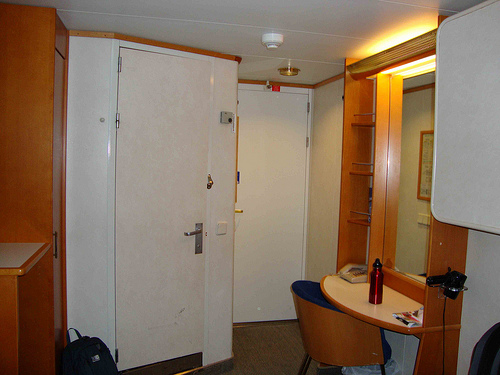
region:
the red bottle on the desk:
[368, 257, 383, 305]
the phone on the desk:
[337, 261, 367, 283]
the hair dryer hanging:
[425, 265, 466, 374]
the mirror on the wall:
[381, 60, 435, 285]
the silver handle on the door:
[182, 230, 200, 235]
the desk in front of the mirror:
[319, 273, 424, 333]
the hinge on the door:
[117, 55, 122, 71]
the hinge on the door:
[115, 113, 120, 128]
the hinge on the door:
[113, 348, 118, 363]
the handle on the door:
[52, 230, 57, 257]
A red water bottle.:
[366, 258, 384, 305]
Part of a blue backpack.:
[61, 324, 117, 374]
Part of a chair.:
[306, 312, 326, 339]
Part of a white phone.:
[340, 260, 370, 282]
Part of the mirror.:
[408, 149, 423, 201]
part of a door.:
[141, 217, 169, 264]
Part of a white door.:
[263, 192, 283, 237]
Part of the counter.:
[11, 245, 21, 257]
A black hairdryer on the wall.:
[428, 268, 468, 298]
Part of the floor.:
[251, 335, 272, 362]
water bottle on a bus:
[362, 254, 397, 306]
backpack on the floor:
[49, 302, 104, 373]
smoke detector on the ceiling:
[258, 31, 285, 49]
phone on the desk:
[336, 250, 371, 281]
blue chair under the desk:
[285, 266, 400, 371]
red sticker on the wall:
[265, 80, 284, 97]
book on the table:
[393, 303, 430, 333]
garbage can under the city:
[341, 355, 375, 372]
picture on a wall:
[414, 119, 436, 204]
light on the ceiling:
[275, 60, 303, 85]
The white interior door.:
[111, 44, 208, 374]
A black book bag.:
[57, 326, 119, 373]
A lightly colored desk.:
[319, 254, 426, 332]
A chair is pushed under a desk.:
[285, 262, 422, 374]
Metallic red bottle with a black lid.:
[365, 256, 386, 308]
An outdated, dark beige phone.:
[335, 259, 371, 286]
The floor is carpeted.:
[226, 317, 306, 372]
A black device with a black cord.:
[425, 265, 471, 373]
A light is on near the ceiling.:
[339, 17, 442, 84]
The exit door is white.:
[235, 79, 311, 324]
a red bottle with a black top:
[368, 258, 385, 305]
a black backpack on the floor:
[57, 325, 116, 374]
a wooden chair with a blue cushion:
[291, 278, 391, 369]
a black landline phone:
[441, 268, 466, 302]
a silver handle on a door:
[183, 223, 205, 255]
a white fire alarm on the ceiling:
[261, 30, 282, 50]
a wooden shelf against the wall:
[336, 73, 396, 266]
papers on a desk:
[394, 307, 424, 327]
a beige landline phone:
[338, 259, 367, 283]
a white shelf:
[1, 240, 49, 270]